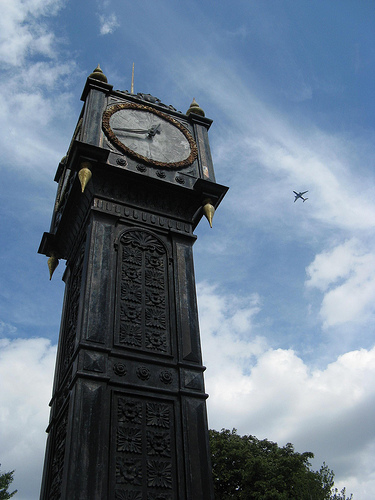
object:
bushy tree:
[205, 427, 360, 499]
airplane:
[288, 188, 313, 207]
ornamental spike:
[202, 202, 219, 228]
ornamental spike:
[44, 253, 61, 283]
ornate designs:
[111, 226, 170, 357]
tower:
[37, 57, 230, 500]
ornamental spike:
[82, 64, 107, 75]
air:
[228, 0, 375, 500]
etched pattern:
[109, 383, 189, 499]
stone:
[40, 343, 213, 498]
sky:
[0, 0, 372, 499]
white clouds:
[301, 233, 372, 334]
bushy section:
[206, 425, 355, 500]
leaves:
[204, 424, 355, 499]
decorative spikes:
[77, 163, 94, 194]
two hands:
[106, 119, 168, 142]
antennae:
[129, 63, 134, 96]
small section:
[92, 189, 192, 239]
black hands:
[112, 123, 145, 135]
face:
[104, 94, 198, 179]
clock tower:
[36, 57, 231, 500]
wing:
[297, 188, 310, 194]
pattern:
[106, 223, 176, 360]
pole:
[128, 58, 136, 93]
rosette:
[110, 357, 132, 380]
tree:
[203, 425, 357, 500]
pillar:
[38, 204, 216, 498]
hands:
[150, 117, 167, 134]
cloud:
[0, 332, 61, 499]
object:
[201, 201, 219, 229]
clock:
[99, 99, 199, 174]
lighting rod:
[127, 51, 138, 96]